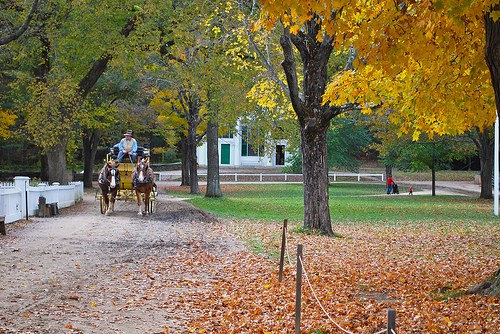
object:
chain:
[295, 254, 390, 333]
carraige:
[94, 143, 159, 219]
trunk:
[298, 128, 332, 238]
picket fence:
[0, 175, 85, 226]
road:
[0, 183, 257, 333]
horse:
[97, 161, 121, 216]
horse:
[129, 155, 154, 217]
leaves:
[287, 23, 302, 36]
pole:
[292, 241, 303, 334]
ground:
[0, 165, 499, 332]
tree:
[201, 1, 500, 237]